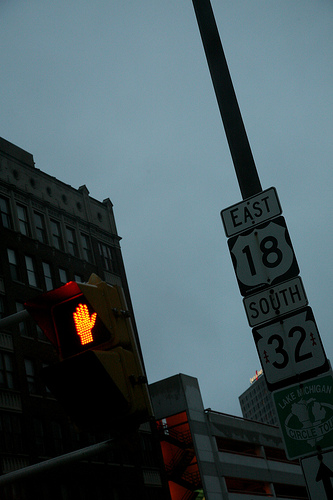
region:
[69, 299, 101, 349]
glowing neon orange stop hand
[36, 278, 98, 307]
reflection of the glowing hand, top of traffic light case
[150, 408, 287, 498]
a glowing red light from i know not where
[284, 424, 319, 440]
the word CIRCLE on a grimy sign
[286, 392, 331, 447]
a monochrome graphic of the states around lake michigan, with water damage straight down the middle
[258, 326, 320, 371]
two funky arrows pointing further on the sides of a 32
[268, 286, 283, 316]
two big bolts holding down the word SOUTH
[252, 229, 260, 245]
slight rust drip stains from the top bolt of a highway 81 sign, going east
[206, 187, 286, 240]
EAST in a rectangle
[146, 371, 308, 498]
multi-floored parking garage with water damage at the top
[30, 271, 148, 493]
an orange traffic sign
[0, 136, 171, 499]
a very tall building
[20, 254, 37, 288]
a window in a building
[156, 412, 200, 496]
stairs in a building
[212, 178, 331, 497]
a very tall street sign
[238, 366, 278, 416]
another building a very far distance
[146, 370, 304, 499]
a building in a distance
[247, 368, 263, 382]
a sign on top of a building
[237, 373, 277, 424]
building with many windows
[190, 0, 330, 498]
a tall post with signs on it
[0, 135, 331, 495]
a dark big building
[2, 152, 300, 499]
a lot of windows on the building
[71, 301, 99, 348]
a hand light on the building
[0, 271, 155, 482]
red and yellow light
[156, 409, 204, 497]
a black stair case way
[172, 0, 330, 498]
a black poll sign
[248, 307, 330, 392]
a number thirty two on it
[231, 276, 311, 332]
a sign read south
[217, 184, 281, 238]
a sign read east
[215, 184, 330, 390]
all the sign is black and white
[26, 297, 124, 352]
a don't cross sign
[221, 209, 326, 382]
highway signs affixed to a lamp post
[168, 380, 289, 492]
a parking garage in the background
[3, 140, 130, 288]
the top of a tall building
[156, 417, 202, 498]
a staircase in the parking garage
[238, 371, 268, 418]
the top of a very tall building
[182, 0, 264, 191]
lamp post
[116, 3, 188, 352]
the sky is overcast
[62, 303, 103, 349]
an illuminated hand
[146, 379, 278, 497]
a rain soaked parking garage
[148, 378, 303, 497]
A parking garage.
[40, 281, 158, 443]
An electric crosswalk sign.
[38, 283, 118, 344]
The sign says don't cross.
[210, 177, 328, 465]
Several street signs on a pole.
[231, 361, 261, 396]
An electric sign on top of a building.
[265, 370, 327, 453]
A sign about Lake Michigan.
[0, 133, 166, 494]
A multistory building.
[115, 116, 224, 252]
The sky is overcast.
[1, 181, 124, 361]
The building has a lot of windows.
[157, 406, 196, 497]
A staircase in the parking garage.